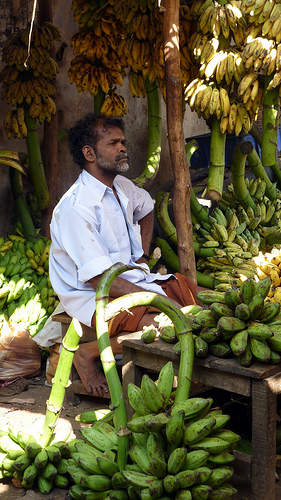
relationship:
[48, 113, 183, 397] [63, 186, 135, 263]
man in shirt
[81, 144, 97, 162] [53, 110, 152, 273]
ear of man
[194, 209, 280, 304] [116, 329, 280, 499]
bananas on table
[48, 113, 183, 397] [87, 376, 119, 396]
man has toes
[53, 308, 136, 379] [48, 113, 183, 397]
stool has man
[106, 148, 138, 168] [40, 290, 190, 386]
mouth on man seated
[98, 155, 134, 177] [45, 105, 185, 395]
beard on man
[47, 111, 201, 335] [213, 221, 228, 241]
man selling banana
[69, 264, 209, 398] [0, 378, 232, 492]
stem on banana